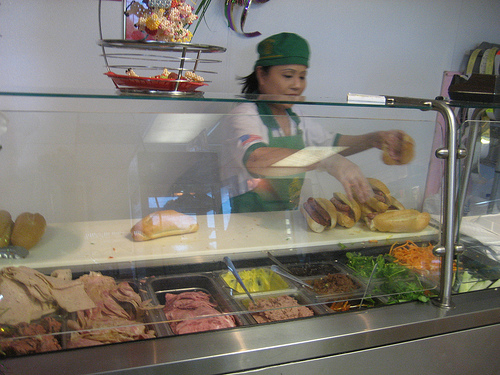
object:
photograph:
[0, 0, 500, 375]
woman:
[218, 33, 403, 213]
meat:
[161, 291, 236, 336]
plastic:
[0, 92, 448, 360]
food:
[0, 209, 13, 248]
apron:
[220, 101, 306, 214]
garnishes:
[240, 295, 312, 326]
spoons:
[220, 256, 256, 307]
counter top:
[0, 209, 440, 268]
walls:
[0, 0, 500, 222]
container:
[211, 264, 298, 299]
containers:
[143, 273, 251, 338]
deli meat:
[35, 271, 98, 312]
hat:
[253, 32, 311, 67]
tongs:
[0, 244, 29, 260]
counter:
[0, 209, 443, 273]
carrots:
[388, 240, 398, 255]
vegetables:
[364, 274, 439, 309]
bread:
[129, 209, 197, 241]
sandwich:
[299, 196, 337, 233]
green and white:
[251, 107, 267, 123]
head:
[256, 32, 311, 110]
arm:
[227, 114, 332, 177]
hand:
[324, 154, 375, 203]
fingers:
[337, 177, 353, 201]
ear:
[254, 65, 266, 85]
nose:
[291, 77, 301, 90]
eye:
[282, 73, 293, 77]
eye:
[299, 76, 305, 80]